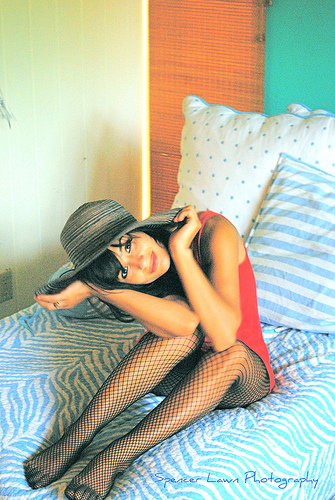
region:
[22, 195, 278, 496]
a woman sitting on a bed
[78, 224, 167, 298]
a woman with black hair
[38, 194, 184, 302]
a woman wearing a hat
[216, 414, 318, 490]
blue and white bed spread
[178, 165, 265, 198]
a white pillow case with blue dots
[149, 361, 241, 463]
a woman wearing hose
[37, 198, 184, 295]
A gray striped hat on a girl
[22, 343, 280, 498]
Fishnet stockings on a girl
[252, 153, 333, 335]
A blue and white striped pillow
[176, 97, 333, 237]
A white pillow with blue spots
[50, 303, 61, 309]
A ring on a girl's finger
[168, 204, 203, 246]
A hand holding the rim of a hat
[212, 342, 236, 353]
A girl's elbow on her knee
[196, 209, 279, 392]
A red sleeveless dress on a girl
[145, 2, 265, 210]
A bamboo covering on a wall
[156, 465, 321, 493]
A photographer's name on a photograph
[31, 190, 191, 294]
The hat the girl is wearing.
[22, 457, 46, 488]
The toes on the girl's left foot.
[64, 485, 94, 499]
The toes on the girl's right foot.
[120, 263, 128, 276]
The girl's left eye.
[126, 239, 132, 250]
The girl's right eye.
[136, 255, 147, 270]
The nose of the girl.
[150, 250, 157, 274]
The mouth of the girl.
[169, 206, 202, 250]
The girl's right hand.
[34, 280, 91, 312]
The girl's left hand.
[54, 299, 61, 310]
The ring on the girl's finger.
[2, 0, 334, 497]
corner of brightly lit bedroom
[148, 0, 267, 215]
wood blinds covering long window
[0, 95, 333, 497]
three pillows on head of bed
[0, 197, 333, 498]
woman sitting up on top of bed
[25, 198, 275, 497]
woman with two hands on hat brim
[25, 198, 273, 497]
woman in fish net stockings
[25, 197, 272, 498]
woman in red sleeveless dress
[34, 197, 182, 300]
striped hat with wide floppy brim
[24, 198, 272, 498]
woman with tilted head under hat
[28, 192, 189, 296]
Hat on a lady's head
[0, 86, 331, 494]
A woman sitting on a bed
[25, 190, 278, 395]
Woman wearing a short red dress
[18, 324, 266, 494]
The stockings are black and fishnet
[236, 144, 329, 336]
Blue and white stripes on a pillow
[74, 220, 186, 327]
Woman has black hair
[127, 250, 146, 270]
Nose on lady's face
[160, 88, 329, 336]
Pillows are on the bed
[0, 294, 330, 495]
A blue and white bedspread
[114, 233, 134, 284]
A pair of dark eyes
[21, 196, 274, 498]
Woman sitting on a bed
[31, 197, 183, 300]
Hat on woman's head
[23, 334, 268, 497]
Textured stockings on woman's legs